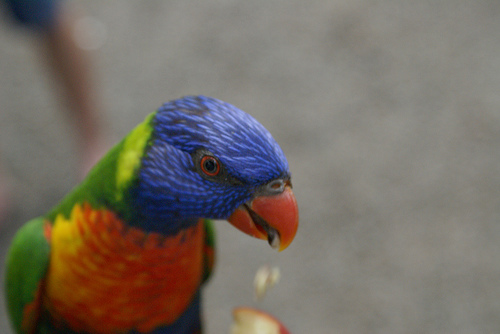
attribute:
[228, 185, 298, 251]
beak — orange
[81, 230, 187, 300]
chest — orange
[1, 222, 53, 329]
wing — green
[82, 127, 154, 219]
neck — green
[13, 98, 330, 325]
bird — blue, green, orange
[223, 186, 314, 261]
beak — red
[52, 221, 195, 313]
feathers — yellow, orange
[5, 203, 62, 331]
wing — green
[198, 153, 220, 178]
eye — black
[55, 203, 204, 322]
breast — yellow, orange, red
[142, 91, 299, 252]
head — blue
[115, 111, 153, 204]
strip — yellow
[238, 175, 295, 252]
beak — orange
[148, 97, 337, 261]
head — black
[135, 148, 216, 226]
cheek — blue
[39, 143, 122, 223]
back — green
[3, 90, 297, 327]
bird — green, yellow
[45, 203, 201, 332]
feathers — orange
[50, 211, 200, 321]
chest — yellow, orange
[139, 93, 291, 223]
feathers — blue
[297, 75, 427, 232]
background — blurry